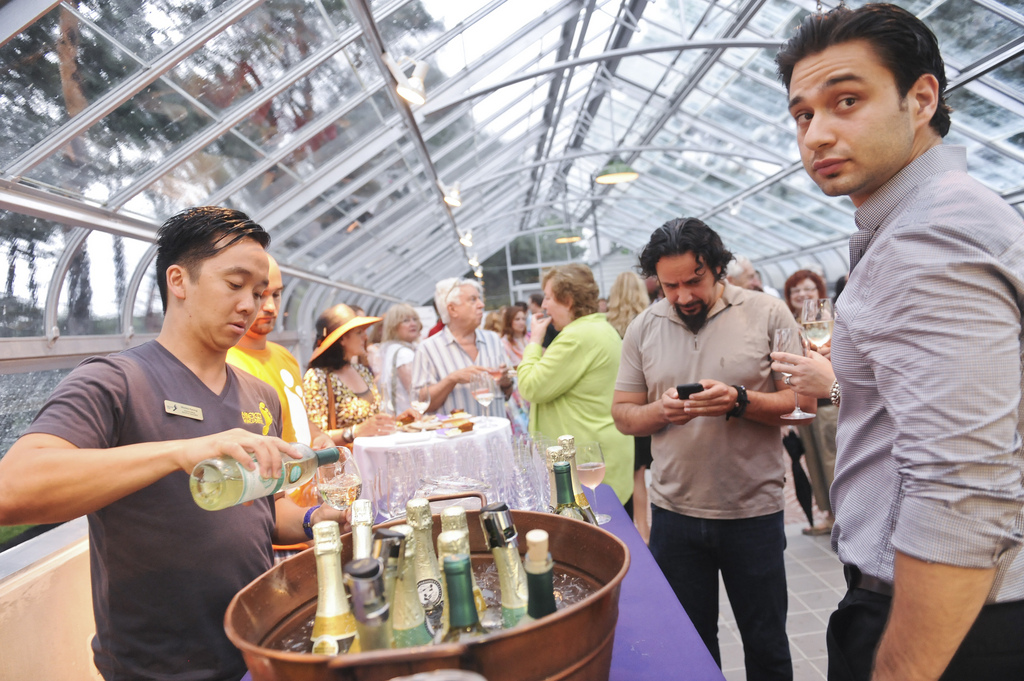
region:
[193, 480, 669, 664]
gold bucket on table top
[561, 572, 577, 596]
ice in golde bucket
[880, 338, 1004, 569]
rolled up shirt sleeve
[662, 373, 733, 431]
smart phone in man's hand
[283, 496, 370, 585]
white cover on bottle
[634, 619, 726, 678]
purple table top cover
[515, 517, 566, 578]
wine cork in bottle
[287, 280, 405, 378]
wide brimmed gold hat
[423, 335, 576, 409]
food in man's hand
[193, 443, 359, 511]
the wine bottle has a white and green label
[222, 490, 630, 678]
the wine bottles in the copper tub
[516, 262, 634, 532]
the woman wearing a green jacket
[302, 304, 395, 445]
the woman is wearing a hat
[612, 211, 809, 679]
the man has dark hair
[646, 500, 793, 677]
the pants are black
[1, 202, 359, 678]
the man is pouring wine into a glass from the wine bottle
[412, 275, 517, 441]
the man is elderly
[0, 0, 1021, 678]
the room has a curved glass ceiling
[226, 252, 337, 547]
the man wearing an orange shirt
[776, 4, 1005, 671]
Man with light colored shirt and dark pants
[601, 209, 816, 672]
Bearded man looking at cell phone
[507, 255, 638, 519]
Woman in green top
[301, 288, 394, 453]
Woman with flowered top and straw hat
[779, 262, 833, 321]
Head of woman with short red hair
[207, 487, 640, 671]
Copper bucket filled with wine bottles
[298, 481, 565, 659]
Wine bottles in copper kettle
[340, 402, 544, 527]
Round table with white tablecloth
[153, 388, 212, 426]
Name tag on man's shirt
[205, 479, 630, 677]
bucket on the table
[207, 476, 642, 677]
bucket full of bottles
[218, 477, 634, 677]
bucket on table is gold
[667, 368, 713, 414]
cell phone in man's hand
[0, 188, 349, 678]
man pouring from a bottle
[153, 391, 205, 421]
man wearing name tag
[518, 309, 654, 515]
woman wearing long sleeve shirt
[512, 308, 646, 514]
woman's shirt is green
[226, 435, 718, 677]
purple tablecloth on table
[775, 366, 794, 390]
ring on woman's hand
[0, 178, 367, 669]
man serving wine on a glass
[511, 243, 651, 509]
woman wears green sweater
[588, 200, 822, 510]
man holding a cell phone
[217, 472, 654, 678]
a container with liquor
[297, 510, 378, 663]
the bottle is close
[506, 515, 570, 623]
bottle has a cork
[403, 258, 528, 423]
man with black hair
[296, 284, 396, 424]
woman wears a hat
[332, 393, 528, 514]
table with white tablecloth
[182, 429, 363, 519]
a bottle of white wine